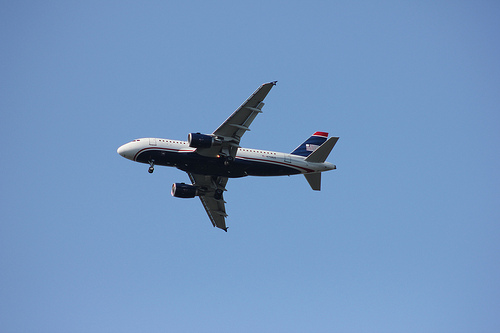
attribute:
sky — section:
[3, 0, 497, 140]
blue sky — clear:
[39, 40, 498, 141]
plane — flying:
[116, 78, 340, 233]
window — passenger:
[159, 139, 166, 142]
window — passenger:
[165, 138, 170, 142]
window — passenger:
[172, 140, 176, 144]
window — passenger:
[183, 142, 188, 145]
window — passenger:
[238, 147, 243, 152]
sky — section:
[281, 27, 436, 74]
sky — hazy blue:
[348, 62, 413, 89]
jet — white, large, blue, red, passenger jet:
[116, 81, 339, 231]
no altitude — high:
[307, 44, 447, 241]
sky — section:
[2, 3, 498, 77]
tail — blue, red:
[293, 132, 330, 159]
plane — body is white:
[104, 75, 346, 246]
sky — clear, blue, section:
[14, 14, 483, 331]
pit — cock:
[113, 128, 149, 163]